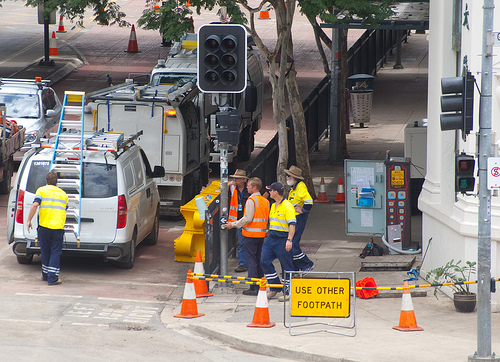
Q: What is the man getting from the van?
A: A ladder.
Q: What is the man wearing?
A: A reflective vest.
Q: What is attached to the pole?
A: Traffic lights.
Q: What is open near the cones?
A: An utility box.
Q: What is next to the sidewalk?
A: An utility fan.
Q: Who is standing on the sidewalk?
A: Four men.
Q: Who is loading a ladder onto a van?
A: A man.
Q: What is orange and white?
A: Safety cones.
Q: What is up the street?
A: Safety cones.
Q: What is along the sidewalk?
A: Fencing.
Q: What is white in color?
A: A building.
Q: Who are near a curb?
A: Construction workers.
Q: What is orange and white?
A: Traffic cones.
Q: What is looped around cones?
A: Caution tape.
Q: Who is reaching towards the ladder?
A: A man.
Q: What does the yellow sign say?
A: Use other footpath.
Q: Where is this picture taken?
A: A street corner.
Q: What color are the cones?
A: Orange.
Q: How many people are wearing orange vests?
A: Two.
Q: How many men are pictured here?
A: Five.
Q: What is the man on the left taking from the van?
A: Ladder.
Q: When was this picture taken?
A: Daytime.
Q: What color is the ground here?
A: Grey.